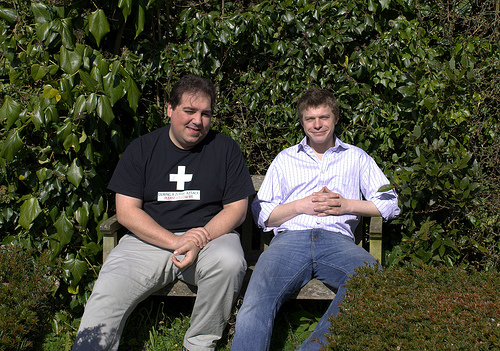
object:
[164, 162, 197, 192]
cross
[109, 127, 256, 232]
shirt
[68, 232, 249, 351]
jeans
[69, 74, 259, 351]
man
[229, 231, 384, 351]
jeans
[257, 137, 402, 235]
shirt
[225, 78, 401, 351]
man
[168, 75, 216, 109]
hair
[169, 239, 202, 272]
hands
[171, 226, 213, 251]
hand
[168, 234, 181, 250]
wrist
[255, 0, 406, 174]
trees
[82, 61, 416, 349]
men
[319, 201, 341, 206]
fingers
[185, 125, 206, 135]
smile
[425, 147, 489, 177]
shrubs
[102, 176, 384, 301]
bench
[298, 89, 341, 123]
light hair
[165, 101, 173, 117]
ear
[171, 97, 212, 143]
face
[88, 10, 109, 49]
leaf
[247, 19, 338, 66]
bush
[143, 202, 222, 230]
belly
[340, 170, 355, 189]
stripes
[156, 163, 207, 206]
logo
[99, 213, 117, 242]
arm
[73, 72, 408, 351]
each other